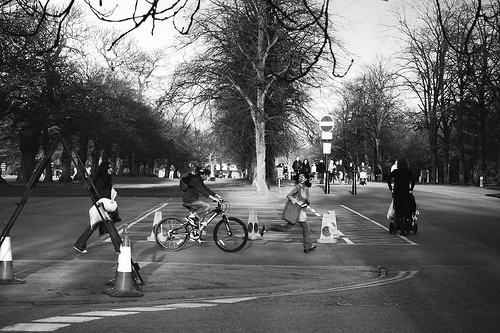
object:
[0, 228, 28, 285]
safety cone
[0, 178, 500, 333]
street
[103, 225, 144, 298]
cone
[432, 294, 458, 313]
beer